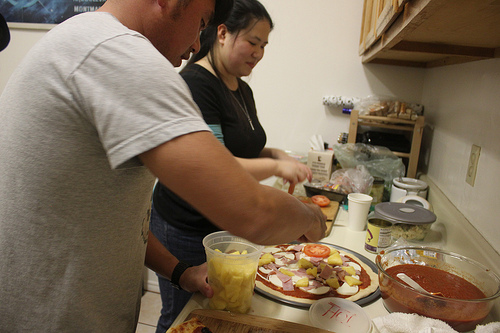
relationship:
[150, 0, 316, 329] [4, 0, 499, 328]
woman in kitchen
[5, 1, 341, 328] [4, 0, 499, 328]
man in kitchen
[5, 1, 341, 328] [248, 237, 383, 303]
man making pizza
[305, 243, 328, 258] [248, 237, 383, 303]
slice on pizza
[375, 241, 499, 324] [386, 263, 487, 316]
bowl with sauce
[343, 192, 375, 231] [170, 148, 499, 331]
cup on table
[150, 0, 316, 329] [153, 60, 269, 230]
woman wears top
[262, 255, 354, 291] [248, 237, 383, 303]
ham over pizza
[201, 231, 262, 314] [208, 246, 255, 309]
container with cheese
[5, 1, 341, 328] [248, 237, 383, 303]
man preparing pizza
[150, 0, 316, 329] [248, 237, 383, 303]
woman preparing pizza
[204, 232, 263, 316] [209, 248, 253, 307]
container with pineapple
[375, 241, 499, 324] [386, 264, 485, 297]
bowl with sauce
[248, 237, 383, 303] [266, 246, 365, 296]
pizza with cheese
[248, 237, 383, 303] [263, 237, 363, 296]
pizza with meat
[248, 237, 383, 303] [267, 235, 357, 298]
pizza with veggies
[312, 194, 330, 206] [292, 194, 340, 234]
slice on cutting board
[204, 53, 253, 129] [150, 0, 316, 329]
necklace worn by woman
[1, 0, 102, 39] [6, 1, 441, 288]
picture hanging on wall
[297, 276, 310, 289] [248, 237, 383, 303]
piece on pizza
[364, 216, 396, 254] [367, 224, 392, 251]
can with label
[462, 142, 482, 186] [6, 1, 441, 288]
switch plate on wall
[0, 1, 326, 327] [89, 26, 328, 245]
man has arm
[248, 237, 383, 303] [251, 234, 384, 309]
pizza on tray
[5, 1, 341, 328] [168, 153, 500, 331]
man at counter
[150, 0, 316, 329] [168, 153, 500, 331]
woman at counter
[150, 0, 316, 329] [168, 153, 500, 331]
woman standing at counter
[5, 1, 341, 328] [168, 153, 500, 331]
man standing at counter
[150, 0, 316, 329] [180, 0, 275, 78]
woman with hair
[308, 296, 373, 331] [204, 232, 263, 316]
lid for container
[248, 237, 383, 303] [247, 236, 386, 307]
pizza on pan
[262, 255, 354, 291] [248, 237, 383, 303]
ham on pizza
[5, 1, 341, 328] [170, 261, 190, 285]
man wearing wrist watch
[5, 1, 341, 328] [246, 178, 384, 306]
man preparing food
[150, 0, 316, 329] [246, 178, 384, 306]
woman preparing food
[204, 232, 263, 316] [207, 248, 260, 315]
container with food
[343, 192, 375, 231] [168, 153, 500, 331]
cup on counter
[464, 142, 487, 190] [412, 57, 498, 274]
outlet on wall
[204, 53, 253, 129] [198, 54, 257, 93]
necklace around neck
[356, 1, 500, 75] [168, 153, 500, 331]
cabinets over counter